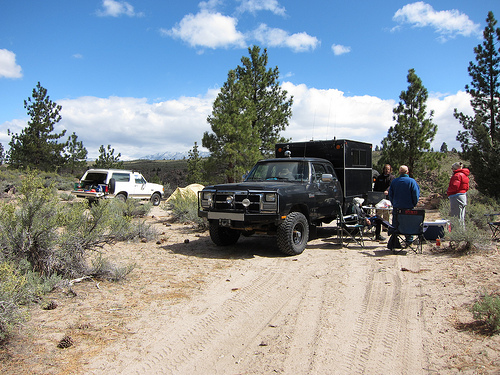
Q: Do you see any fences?
A: No, there are no fences.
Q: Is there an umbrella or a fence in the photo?
A: No, there are no fences or umbrellas.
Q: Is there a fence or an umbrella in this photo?
A: No, there are no fences or umbrellas.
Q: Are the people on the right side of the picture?
A: Yes, the people are on the right of the image.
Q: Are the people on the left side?
A: No, the people are on the right of the image.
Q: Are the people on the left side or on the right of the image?
A: The people are on the right of the image.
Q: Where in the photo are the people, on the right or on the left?
A: The people are on the right of the image.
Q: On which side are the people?
A: The people are on the right of the image.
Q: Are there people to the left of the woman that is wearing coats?
A: Yes, there are people to the left of the woman.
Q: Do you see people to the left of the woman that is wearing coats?
A: Yes, there are people to the left of the woman.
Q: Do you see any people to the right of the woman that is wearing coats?
A: No, the people are to the left of the woman.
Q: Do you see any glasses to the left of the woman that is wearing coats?
A: No, there are people to the left of the woman.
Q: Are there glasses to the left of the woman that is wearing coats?
A: No, there are people to the left of the woman.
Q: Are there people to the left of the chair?
A: Yes, there are people to the left of the chair.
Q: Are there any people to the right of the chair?
A: No, the people are to the left of the chair.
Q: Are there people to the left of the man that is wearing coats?
A: Yes, there are people to the left of the man.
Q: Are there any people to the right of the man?
A: No, the people are to the left of the man.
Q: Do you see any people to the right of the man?
A: No, the people are to the left of the man.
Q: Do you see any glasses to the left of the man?
A: No, there are people to the left of the man.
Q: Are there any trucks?
A: Yes, there is a truck.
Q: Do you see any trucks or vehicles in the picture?
A: Yes, there is a truck.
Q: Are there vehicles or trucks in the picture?
A: Yes, there is a truck.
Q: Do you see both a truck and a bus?
A: No, there is a truck but no buses.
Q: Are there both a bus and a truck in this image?
A: No, there is a truck but no buses.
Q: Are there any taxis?
A: No, there are no taxis.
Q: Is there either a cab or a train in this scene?
A: No, there are no taxis or trains.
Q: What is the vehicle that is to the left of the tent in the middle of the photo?
A: The vehicle is a truck.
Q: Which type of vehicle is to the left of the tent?
A: The vehicle is a truck.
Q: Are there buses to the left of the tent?
A: No, there is a truck to the left of the tent.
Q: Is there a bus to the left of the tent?
A: No, there is a truck to the left of the tent.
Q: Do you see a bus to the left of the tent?
A: No, there is a truck to the left of the tent.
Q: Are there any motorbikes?
A: No, there are no motorbikes.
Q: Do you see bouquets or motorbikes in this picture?
A: No, there are no motorbikes or bouquets.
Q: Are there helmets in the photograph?
A: No, there are no helmets.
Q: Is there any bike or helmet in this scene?
A: No, there are no helmets or bikes.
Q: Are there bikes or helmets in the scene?
A: No, there are no helmets or bikes.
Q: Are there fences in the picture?
A: No, there are no fences.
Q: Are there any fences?
A: No, there are no fences.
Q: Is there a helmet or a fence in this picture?
A: No, there are no fences or helmets.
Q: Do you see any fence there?
A: No, there are no fences.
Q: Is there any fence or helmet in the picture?
A: No, there are no fences or helmets.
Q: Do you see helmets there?
A: No, there are no helmets.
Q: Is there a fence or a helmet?
A: No, there are no helmets or fences.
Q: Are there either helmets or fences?
A: No, there are no helmets or fences.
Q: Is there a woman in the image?
A: Yes, there is a woman.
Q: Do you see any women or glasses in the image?
A: Yes, there is a woman.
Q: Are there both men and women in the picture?
A: Yes, there are both a woman and a man.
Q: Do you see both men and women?
A: Yes, there are both a woman and a man.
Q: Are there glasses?
A: No, there are no glasses.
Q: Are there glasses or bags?
A: No, there are no glasses or bags.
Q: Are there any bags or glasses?
A: No, there are no glasses or bags.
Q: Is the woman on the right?
A: Yes, the woman is on the right of the image.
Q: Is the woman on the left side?
A: No, the woman is on the right of the image.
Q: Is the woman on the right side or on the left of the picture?
A: The woman is on the right of the image.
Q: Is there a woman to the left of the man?
A: Yes, there is a woman to the left of the man.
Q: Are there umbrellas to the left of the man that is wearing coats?
A: No, there is a woman to the left of the man.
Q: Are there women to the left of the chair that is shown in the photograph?
A: Yes, there is a woman to the left of the chair.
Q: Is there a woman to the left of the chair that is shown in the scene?
A: Yes, there is a woman to the left of the chair.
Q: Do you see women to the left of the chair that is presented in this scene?
A: Yes, there is a woman to the left of the chair.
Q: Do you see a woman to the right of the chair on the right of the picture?
A: No, the woman is to the left of the chair.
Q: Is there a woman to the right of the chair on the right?
A: No, the woman is to the left of the chair.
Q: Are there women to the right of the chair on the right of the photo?
A: No, the woman is to the left of the chair.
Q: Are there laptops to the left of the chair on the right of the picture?
A: No, there is a woman to the left of the chair.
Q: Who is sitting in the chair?
A: The woman is sitting in the chair.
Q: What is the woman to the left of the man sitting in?
A: The woman is sitting in the chair.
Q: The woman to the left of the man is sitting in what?
A: The woman is sitting in the chair.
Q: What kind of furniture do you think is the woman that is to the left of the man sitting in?
A: The woman is sitting in the chair.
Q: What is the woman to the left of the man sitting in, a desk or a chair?
A: The woman is sitting in a chair.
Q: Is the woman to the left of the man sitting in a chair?
A: Yes, the woman is sitting in a chair.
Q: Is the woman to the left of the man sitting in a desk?
A: No, the woman is sitting in a chair.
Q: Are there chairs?
A: Yes, there is a chair.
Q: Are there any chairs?
A: Yes, there is a chair.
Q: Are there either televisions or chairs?
A: Yes, there is a chair.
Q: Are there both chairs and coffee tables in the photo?
A: No, there is a chair but no coffee tables.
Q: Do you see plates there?
A: No, there are no plates.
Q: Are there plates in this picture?
A: No, there are no plates.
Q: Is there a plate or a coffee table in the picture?
A: No, there are no plates or coffee tables.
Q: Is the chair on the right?
A: Yes, the chair is on the right of the image.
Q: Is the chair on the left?
A: No, the chair is on the right of the image.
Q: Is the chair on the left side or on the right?
A: The chair is on the right of the image.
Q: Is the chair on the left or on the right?
A: The chair is on the right of the image.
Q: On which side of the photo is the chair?
A: The chair is on the right of the image.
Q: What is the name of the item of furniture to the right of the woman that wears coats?
A: The piece of furniture is a chair.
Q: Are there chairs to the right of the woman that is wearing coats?
A: Yes, there is a chair to the right of the woman.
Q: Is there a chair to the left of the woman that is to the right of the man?
A: No, the chair is to the right of the woman.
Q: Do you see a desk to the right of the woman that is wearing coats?
A: No, there is a chair to the right of the woman.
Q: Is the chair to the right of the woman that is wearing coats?
A: Yes, the chair is to the right of the woman.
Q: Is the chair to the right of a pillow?
A: No, the chair is to the right of the woman.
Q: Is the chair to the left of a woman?
A: No, the chair is to the right of a woman.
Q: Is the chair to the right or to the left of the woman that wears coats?
A: The chair is to the right of the woman.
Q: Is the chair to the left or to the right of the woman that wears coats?
A: The chair is to the right of the woman.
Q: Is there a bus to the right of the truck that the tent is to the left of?
A: No, there is a chair to the right of the truck.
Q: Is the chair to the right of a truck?
A: Yes, the chair is to the right of a truck.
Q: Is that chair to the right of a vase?
A: No, the chair is to the right of a truck.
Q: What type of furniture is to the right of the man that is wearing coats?
A: The piece of furniture is a chair.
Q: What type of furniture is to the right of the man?
A: The piece of furniture is a chair.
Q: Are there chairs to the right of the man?
A: Yes, there is a chair to the right of the man.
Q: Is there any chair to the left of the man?
A: No, the chair is to the right of the man.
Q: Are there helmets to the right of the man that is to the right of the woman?
A: No, there is a chair to the right of the man.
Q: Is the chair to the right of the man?
A: Yes, the chair is to the right of the man.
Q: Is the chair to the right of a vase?
A: No, the chair is to the right of the man.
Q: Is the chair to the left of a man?
A: No, the chair is to the right of a man.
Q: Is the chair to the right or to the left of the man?
A: The chair is to the right of the man.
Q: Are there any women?
A: Yes, there is a woman.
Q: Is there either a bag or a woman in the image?
A: Yes, there is a woman.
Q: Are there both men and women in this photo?
A: Yes, there are both a woman and a man.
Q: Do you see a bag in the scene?
A: No, there are no bags.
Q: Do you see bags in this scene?
A: No, there are no bags.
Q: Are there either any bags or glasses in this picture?
A: No, there are no bags or glasses.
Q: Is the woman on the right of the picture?
A: Yes, the woman is on the right of the image.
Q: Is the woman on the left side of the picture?
A: No, the woman is on the right of the image.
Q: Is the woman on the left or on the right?
A: The woman is on the right of the image.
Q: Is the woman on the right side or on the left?
A: The woman is on the right of the image.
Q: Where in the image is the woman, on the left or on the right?
A: The woman is on the right of the image.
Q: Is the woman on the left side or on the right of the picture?
A: The woman is on the right of the image.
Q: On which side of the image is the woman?
A: The woman is on the right of the image.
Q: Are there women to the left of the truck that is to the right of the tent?
A: No, the woman is to the right of the truck.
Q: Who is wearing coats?
A: The woman is wearing coats.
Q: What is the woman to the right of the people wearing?
A: The woman is wearing coats.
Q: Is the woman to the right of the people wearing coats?
A: Yes, the woman is wearing coats.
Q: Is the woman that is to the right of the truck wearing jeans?
A: No, the woman is wearing coats.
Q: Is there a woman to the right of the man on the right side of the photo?
A: Yes, there is a woman to the right of the man.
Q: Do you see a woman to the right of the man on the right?
A: Yes, there is a woman to the right of the man.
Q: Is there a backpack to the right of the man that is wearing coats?
A: No, there is a woman to the right of the man.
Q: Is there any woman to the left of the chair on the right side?
A: Yes, there is a woman to the left of the chair.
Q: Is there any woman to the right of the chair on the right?
A: No, the woman is to the left of the chair.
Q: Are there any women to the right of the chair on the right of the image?
A: No, the woman is to the left of the chair.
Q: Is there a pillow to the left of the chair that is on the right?
A: No, there is a woman to the left of the chair.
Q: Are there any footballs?
A: No, there are no footballs.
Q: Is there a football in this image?
A: No, there are no footballs.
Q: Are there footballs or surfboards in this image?
A: No, there are no footballs or surfboards.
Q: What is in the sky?
A: The clouds are in the sky.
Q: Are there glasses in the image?
A: No, there are no glasses.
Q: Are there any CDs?
A: No, there are no cds.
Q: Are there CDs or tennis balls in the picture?
A: No, there are no CDs or tennis balls.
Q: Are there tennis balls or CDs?
A: No, there are no CDs or tennis balls.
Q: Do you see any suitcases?
A: No, there are no suitcases.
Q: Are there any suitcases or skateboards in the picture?
A: No, there are no suitcases or skateboards.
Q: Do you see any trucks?
A: Yes, there is a truck.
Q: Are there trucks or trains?
A: Yes, there is a truck.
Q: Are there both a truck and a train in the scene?
A: No, there is a truck but no trains.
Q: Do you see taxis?
A: No, there are no taxis.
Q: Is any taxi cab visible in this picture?
A: No, there are no taxis.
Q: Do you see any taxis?
A: No, there are no taxis.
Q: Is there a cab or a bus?
A: No, there are no taxis or buses.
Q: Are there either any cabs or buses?
A: No, there are no cabs or buses.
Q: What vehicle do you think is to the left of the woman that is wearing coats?
A: The vehicle is a truck.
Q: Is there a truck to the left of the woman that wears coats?
A: Yes, there is a truck to the left of the woman.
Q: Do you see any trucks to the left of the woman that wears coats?
A: Yes, there is a truck to the left of the woman.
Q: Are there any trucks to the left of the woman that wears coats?
A: Yes, there is a truck to the left of the woman.